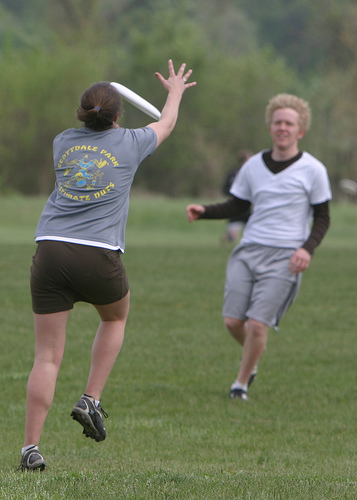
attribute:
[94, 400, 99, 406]
sock — White 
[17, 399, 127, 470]
sneakers — Dirty, black, white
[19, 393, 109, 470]
shoes — White 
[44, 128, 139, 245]
shirt — gray 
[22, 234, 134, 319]
shorts — short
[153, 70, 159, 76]
fingernail — painted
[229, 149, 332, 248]
shirt — white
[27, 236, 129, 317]
shorts — dark 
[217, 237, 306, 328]
shorts — Black, grey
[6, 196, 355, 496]
grass — green 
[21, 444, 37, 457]
sock — white 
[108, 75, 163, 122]
frisbee — white 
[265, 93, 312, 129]
hair — curly, blonde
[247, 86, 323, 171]
person — long-sleeved 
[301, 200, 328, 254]
sleeve — black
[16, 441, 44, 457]
socks —  low-cut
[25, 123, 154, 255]
shirt — gray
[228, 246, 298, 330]
shorts — grey